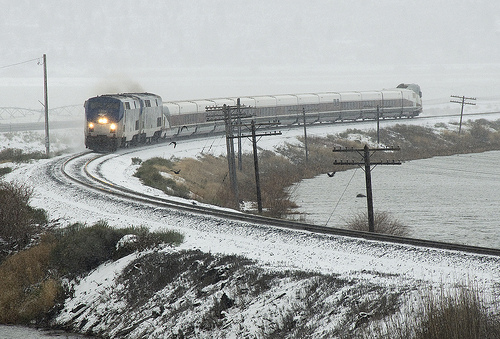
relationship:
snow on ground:
[0, 157, 499, 307] [68, 210, 224, 313]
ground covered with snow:
[31, 168, 106, 303] [426, 207, 473, 237]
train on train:
[83, 83, 426, 154] [81, 85, 169, 153]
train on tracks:
[39, 87, 497, 281] [46, 107, 497, 264]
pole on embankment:
[441, 89, 472, 139] [403, 120, 499, 150]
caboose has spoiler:
[391, 74, 436, 133] [388, 75, 438, 104]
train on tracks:
[83, 83, 426, 154] [69, 143, 392, 265]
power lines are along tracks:
[222, 90, 397, 231] [46, 110, 500, 257]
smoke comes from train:
[101, 72, 157, 91] [45, 52, 452, 164]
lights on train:
[83, 112, 122, 132] [46, 33, 498, 170]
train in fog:
[83, 83, 426, 154] [37, 30, 330, 110]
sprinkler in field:
[1, 100, 88, 123] [2, 98, 82, 156]